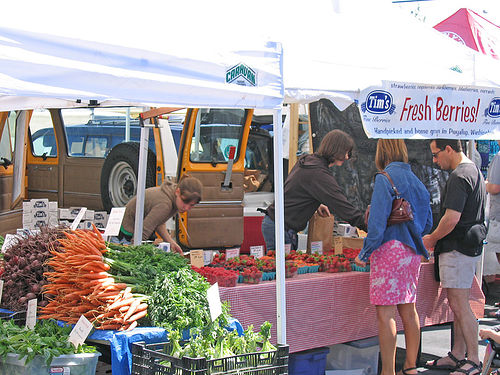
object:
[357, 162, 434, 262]
jacket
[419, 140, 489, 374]
man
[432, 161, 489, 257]
shirt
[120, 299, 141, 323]
carrot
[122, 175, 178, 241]
hoodie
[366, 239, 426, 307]
skirt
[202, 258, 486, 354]
cloth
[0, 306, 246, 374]
tarp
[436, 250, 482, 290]
shorts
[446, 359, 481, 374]
sandal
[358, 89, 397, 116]
sign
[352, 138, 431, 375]
woman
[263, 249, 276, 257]
berry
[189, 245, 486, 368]
table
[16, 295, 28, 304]
radish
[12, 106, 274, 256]
van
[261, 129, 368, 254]
lady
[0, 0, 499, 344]
canopy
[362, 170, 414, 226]
purse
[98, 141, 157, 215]
tire